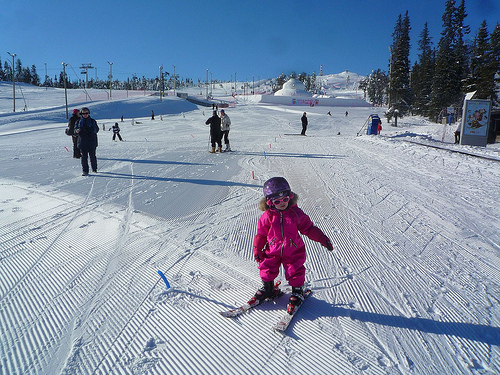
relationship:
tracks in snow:
[12, 197, 140, 321] [28, 112, 473, 374]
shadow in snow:
[328, 287, 500, 339] [28, 112, 473, 374]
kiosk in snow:
[458, 92, 487, 157] [28, 112, 473, 374]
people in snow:
[206, 111, 243, 155] [28, 112, 473, 374]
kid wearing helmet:
[243, 176, 340, 295] [263, 175, 290, 195]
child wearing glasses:
[243, 176, 340, 295] [270, 197, 290, 204]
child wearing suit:
[243, 176, 340, 295] [257, 209, 327, 288]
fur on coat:
[259, 200, 269, 210] [257, 213, 308, 256]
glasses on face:
[80, 112, 91, 118] [78, 110, 92, 120]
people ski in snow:
[206, 111, 243, 155] [28, 112, 473, 374]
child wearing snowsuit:
[243, 176, 340, 295] [257, 209, 327, 288]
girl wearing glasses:
[243, 176, 340, 295] [270, 197, 290, 204]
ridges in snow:
[251, 144, 278, 173] [28, 112, 473, 374]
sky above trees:
[10, 3, 393, 68] [365, 22, 484, 106]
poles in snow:
[246, 134, 285, 180] [28, 112, 473, 374]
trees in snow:
[365, 22, 484, 106] [28, 112, 473, 374]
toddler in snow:
[243, 176, 340, 295] [28, 112, 473, 374]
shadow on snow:
[328, 287, 500, 339] [28, 112, 473, 374]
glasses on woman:
[80, 112, 91, 118] [75, 106, 107, 173]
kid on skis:
[243, 176, 340, 295] [234, 287, 316, 332]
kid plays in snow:
[243, 176, 340, 295] [28, 112, 473, 374]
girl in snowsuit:
[243, 176, 340, 295] [257, 209, 327, 288]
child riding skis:
[243, 176, 340, 295] [234, 287, 316, 332]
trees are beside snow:
[365, 22, 484, 106] [28, 112, 473, 374]